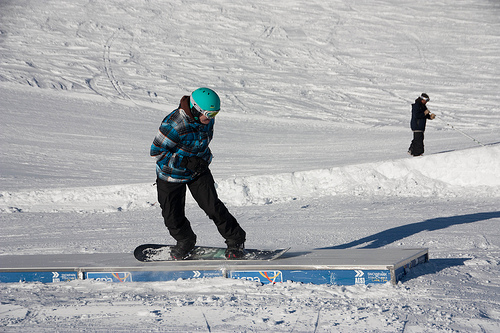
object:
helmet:
[190, 87, 220, 119]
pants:
[153, 168, 246, 246]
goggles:
[204, 110, 218, 119]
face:
[200, 111, 211, 124]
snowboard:
[134, 244, 291, 262]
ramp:
[0, 248, 429, 285]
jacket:
[151, 97, 215, 183]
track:
[102, 27, 131, 101]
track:
[253, 27, 276, 62]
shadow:
[313, 212, 500, 250]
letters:
[355, 278, 366, 285]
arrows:
[354, 270, 365, 277]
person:
[149, 88, 246, 259]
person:
[407, 93, 436, 157]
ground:
[0, 0, 500, 333]